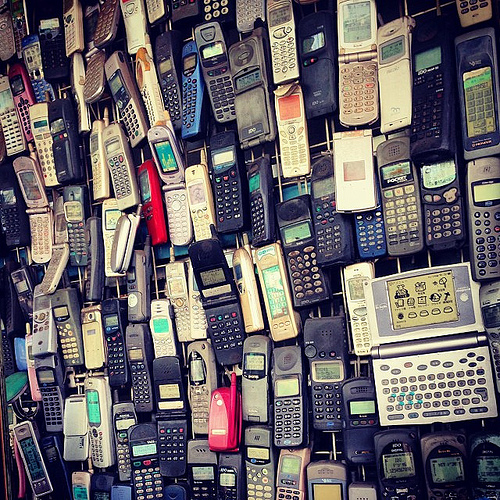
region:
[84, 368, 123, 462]
phones on a wall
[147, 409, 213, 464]
phones on a wall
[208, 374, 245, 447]
phones on a wall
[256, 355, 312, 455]
phones on a wall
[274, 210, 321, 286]
phones on a wall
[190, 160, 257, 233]
phones on a wall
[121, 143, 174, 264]
phones on a wall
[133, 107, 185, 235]
phones on a wall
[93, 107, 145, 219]
phones on a wall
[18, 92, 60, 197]
phones on a wall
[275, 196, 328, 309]
a black hanging cell phone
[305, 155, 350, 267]
a black hanging cell phone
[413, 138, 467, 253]
a black hanging cell phone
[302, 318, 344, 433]
a black hanging cell phone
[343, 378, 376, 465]
a black hanging cell phone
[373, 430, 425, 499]
a black hanging cell phone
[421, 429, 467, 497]
a black hanging cell phone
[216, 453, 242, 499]
a black hanging cell phone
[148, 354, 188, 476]
a black hanging cell phone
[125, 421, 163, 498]
a black hanging cell phone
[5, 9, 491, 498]
a wall of out dated cell phones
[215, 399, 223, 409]
white button on red cell phone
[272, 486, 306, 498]
black buttons on pink cell phone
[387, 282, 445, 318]
black icons on phone screen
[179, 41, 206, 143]
a blue handset with black buttons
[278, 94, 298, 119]
a bright orange phone screen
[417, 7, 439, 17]
white wire hook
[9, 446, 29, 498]
hot pink leather phone strap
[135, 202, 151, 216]
antenna on a flip phone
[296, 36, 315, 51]
black lcd leaking onto screen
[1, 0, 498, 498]
a lot of phones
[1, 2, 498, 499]
a wall of cell phones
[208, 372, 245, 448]
the phone is red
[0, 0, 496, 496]
a wall of old technology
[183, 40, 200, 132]
a blue cell phone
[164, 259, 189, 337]
a silver cell phone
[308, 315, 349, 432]
a black cell phone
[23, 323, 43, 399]
a pink cell phone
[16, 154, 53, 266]
a flip phone on the wall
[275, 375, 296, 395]
a screen of a phone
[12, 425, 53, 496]
a cell phone on the wall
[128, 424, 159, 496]
a cell phone on the wall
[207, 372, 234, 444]
a cell phone on the wall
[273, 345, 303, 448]
a cell phone on the wall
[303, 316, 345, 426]
a cell phone on the wall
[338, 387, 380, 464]
a cell phone on the wall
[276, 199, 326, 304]
a cell phone on the wall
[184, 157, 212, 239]
a cell phone on the wall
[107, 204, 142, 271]
a cell phone on the wall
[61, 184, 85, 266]
a cell phone on the wall